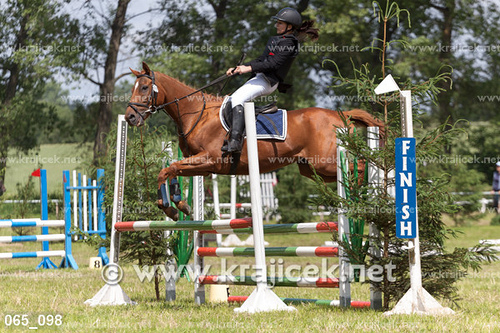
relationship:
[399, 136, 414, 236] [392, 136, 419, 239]
word printed on sign